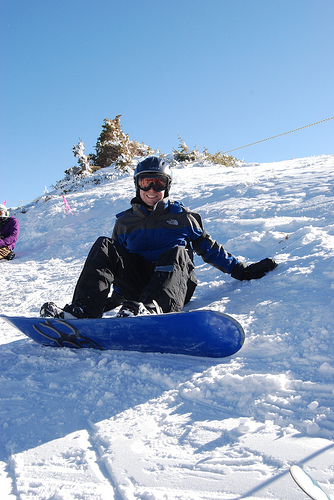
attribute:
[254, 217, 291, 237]
snow — chunky, white, here, shaded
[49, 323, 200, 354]
snowboard — bottom, bnlue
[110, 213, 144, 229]
jacket — brown, here, blue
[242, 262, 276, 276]
glove — black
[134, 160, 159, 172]
helmet — worn, blacky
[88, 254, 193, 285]
pants — black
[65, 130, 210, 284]
man — cutting, fallen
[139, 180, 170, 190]
goggles — black